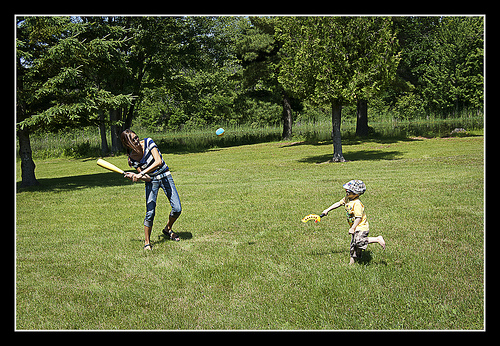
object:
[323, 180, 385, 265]
kid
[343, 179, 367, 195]
hat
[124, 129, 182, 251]
woman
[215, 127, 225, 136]
ball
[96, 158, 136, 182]
bat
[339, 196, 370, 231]
shirt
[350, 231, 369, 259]
shorts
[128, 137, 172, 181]
shirt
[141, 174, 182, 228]
jeans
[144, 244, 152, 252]
sandals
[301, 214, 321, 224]
scoop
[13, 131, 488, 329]
grass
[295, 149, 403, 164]
shadow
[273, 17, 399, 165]
tree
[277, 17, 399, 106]
leaves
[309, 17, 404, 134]
tree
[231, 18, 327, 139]
tree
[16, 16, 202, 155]
tree